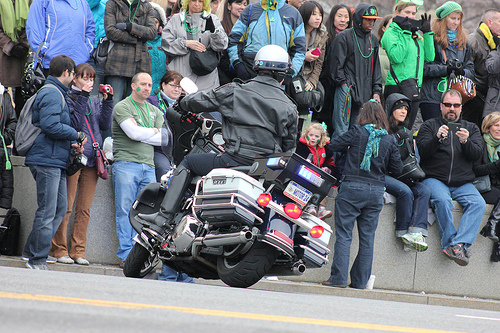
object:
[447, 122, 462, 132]
cellphone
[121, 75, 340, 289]
motorcycle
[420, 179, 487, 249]
jeans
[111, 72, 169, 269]
man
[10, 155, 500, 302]
wall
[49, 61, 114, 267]
people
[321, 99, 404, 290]
people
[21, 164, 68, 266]
jeans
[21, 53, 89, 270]
man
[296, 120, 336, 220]
child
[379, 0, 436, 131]
woman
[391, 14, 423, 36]
scarf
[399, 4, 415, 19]
face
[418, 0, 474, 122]
woman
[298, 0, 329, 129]
woman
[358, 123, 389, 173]
scarf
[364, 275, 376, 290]
cup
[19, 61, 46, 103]
backpack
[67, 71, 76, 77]
glasses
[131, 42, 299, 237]
patrolman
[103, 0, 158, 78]
coat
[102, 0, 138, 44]
arm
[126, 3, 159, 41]
arm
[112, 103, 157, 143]
arm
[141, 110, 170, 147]
arm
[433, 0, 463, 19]
cap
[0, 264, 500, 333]
street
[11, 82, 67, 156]
backpack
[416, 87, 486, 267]
man